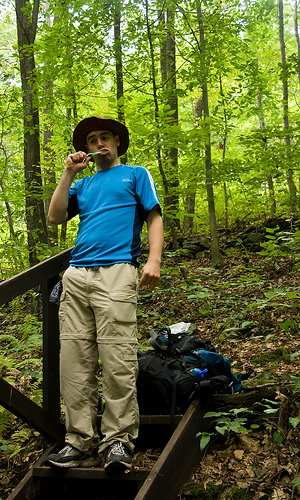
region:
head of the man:
[55, 110, 142, 175]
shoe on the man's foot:
[96, 431, 142, 473]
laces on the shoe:
[101, 433, 129, 463]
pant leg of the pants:
[82, 325, 154, 421]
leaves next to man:
[205, 399, 271, 440]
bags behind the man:
[124, 325, 232, 410]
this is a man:
[45, 116, 191, 476]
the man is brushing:
[35, 87, 179, 268]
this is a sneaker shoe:
[78, 426, 138, 484]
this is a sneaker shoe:
[44, 432, 92, 480]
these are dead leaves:
[207, 447, 242, 478]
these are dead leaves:
[193, 458, 234, 491]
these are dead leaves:
[226, 341, 289, 396]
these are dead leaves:
[213, 443, 263, 493]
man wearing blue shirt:
[28, 103, 166, 463]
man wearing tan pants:
[30, 100, 154, 466]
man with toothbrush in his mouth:
[34, 104, 169, 464]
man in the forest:
[37, 113, 178, 465]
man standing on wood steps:
[39, 112, 191, 457]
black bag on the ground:
[138, 338, 193, 414]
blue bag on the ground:
[188, 345, 241, 390]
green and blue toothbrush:
[82, 142, 107, 163]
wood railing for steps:
[6, 249, 69, 447]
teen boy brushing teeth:
[36, 115, 169, 479]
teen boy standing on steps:
[33, 115, 170, 474]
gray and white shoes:
[38, 438, 135, 473]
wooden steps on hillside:
[4, 396, 212, 499]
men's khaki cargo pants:
[53, 259, 143, 457]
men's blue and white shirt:
[60, 160, 167, 271]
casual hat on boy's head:
[68, 113, 131, 159]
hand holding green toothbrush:
[66, 148, 110, 172]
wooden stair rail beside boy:
[2, 242, 84, 448]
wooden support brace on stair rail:
[2, 371, 72, 447]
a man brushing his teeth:
[61, 107, 132, 178]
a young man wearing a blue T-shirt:
[41, 109, 170, 291]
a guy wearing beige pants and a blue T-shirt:
[41, 98, 176, 479]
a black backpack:
[139, 312, 232, 413]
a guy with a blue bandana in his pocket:
[42, 111, 165, 310]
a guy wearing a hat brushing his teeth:
[51, 107, 146, 179]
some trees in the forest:
[169, 8, 288, 274]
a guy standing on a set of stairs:
[36, 105, 176, 497]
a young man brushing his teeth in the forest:
[27, 91, 254, 229]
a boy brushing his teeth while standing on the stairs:
[24, 113, 166, 495]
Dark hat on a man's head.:
[71, 114, 129, 155]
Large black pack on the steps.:
[133, 321, 242, 407]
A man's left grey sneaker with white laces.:
[103, 441, 133, 469]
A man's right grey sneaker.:
[45, 445, 101, 467]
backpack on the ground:
[148, 324, 230, 391]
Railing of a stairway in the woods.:
[0, 244, 75, 442]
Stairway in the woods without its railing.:
[5, 393, 216, 499]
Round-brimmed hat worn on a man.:
[73, 115, 130, 160]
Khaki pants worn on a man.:
[57, 262, 140, 461]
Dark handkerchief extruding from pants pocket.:
[49, 279, 62, 305]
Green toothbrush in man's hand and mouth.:
[81, 149, 106, 162]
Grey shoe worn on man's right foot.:
[45, 443, 100, 467]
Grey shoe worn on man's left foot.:
[103, 440, 133, 472]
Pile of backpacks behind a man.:
[136, 322, 254, 432]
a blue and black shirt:
[64, 164, 160, 264]